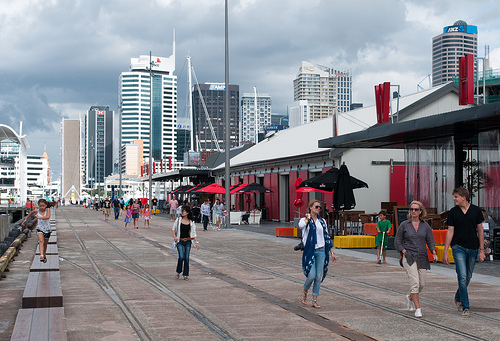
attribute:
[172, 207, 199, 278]
woman — looking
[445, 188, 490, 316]
man — looking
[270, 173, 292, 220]
doors — red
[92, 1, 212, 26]
sky — cloudy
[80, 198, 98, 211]
people — walking